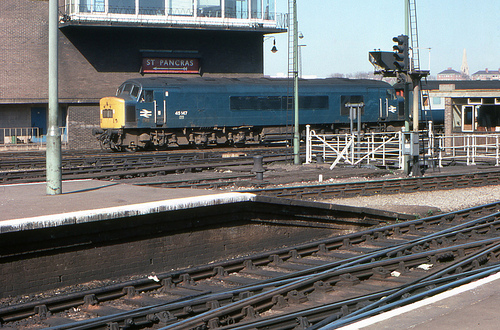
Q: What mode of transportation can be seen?
A: A train.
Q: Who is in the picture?
A: No one.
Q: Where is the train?
A: At a station.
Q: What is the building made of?
A: Brick.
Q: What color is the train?
A: Blue.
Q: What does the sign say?
A: St Pancras.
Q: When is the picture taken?
A: Daytime.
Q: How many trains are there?
A: 1.